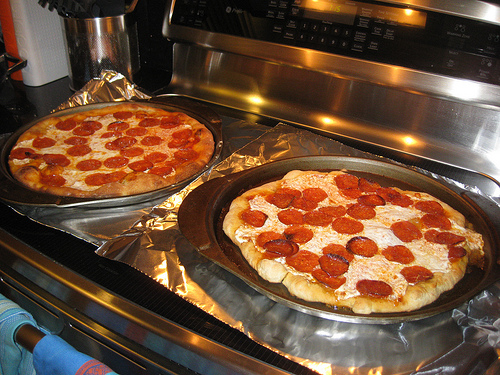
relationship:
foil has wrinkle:
[0, 69, 498, 373] [140, 227, 181, 284]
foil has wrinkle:
[0, 69, 498, 373] [264, 131, 312, 152]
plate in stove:
[164, 179, 239, 272] [170, 1, 498, 136]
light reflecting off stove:
[391, 127, 428, 152] [3, 1, 499, 373]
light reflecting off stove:
[393, 2, 421, 22] [3, 1, 499, 373]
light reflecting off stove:
[308, 112, 339, 129] [3, 1, 499, 373]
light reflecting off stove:
[240, 83, 269, 113] [3, 1, 499, 373]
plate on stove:
[178, 156, 496, 326] [3, 1, 499, 373]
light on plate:
[309, 304, 363, 347] [178, 156, 496, 326]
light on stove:
[240, 90, 419, 149] [3, 1, 499, 373]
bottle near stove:
[41, 3, 159, 97] [3, 1, 499, 373]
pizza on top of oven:
[222, 168, 485, 315] [14, 225, 217, 372]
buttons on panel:
[271, 4, 431, 62] [173, 0, 498, 85]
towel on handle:
[0, 294, 119, 374] [2, 294, 120, 374]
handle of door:
[2, 294, 120, 374] [4, 267, 194, 373]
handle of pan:
[1, 49, 27, 80] [0, 29, 27, 100]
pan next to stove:
[0, 29, 27, 100] [1, 85, 499, 372]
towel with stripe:
[1, 295, 38, 373] [1, 299, 24, 317]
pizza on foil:
[223, 170, 483, 315] [94, 120, 499, 374]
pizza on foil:
[7, 102, 215, 200] [7, 67, 272, 247]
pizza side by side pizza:
[223, 170, 483, 315] [9, 100, 215, 200]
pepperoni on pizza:
[269, 190, 320, 208] [223, 170, 483, 315]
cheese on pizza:
[368, 222, 388, 235] [223, 170, 483, 315]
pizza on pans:
[223, 170, 483, 315] [178, 154, 498, 324]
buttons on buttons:
[276, 53, 470, 170] [162, 24, 500, 177]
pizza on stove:
[222, 168, 485, 315] [3, 1, 499, 373]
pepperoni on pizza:
[316, 251, 347, 274] [223, 170, 483, 315]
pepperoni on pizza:
[288, 247, 320, 277] [222, 136, 489, 323]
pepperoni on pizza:
[331, 212, 361, 234] [214, 162, 485, 321]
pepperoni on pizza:
[273, 181, 335, 271] [176, 141, 498, 348]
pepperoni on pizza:
[263, 182, 301, 209] [214, 162, 485, 321]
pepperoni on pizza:
[352, 271, 393, 306] [1, 97, 223, 206]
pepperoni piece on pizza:
[270, 194, 355, 241] [42, 102, 197, 199]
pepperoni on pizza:
[357, 279, 393, 298] [223, 170, 483, 315]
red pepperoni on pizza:
[308, 204, 351, 234] [223, 170, 483, 315]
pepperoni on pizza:
[399, 263, 442, 286] [214, 162, 485, 321]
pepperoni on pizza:
[324, 200, 378, 232] [265, 144, 442, 309]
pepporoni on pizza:
[258, 228, 303, 259] [214, 162, 485, 321]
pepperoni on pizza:
[269, 190, 296, 206] [223, 170, 483, 315]